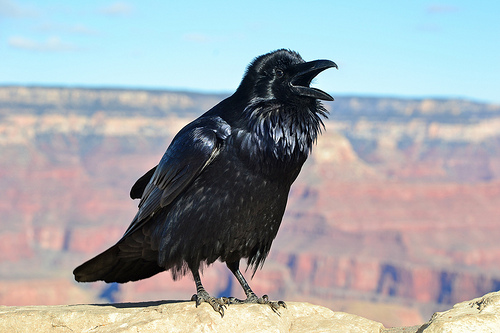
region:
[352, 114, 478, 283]
The inside of the mountain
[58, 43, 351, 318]
The bird is sitting on the mountain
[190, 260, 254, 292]
The legs on the bird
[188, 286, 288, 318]
The feet on the bird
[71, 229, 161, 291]
The tail on the bird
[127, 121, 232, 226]
The wing of the bird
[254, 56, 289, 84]
The eye of the bird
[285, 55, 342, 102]
The beak of the bird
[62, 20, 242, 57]
The sky is clear and blue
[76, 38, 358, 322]
The bird is the color black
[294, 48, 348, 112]
beak of the bird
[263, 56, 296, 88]
eye of the bird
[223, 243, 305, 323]
leg of the bird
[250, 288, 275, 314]
nail of the foot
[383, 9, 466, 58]
blue sky in the background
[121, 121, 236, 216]
black feathers on the bird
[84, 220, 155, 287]
tail feathers of the bird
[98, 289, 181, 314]
shadow on the rock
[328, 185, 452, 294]
blurry rocks in the background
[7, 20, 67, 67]
cloud in the sky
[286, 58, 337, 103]
Bird's Opened Wide Beak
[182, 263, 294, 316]
Sharp Black Bird Claws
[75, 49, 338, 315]
Black Bird Making His Calling Sound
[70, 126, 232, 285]
Silky Soft Black Wings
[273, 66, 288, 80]
Piercing All Black Eyes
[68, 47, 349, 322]
Medium Size Black Bird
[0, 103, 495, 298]
Canyons of in the distance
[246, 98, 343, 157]
Feathered out bird feathers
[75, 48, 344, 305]
Black Bird Standing Tall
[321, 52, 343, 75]
Large Pointed Tip Of Bird's Beak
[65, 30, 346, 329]
The bird's feather are shiny.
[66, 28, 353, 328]
The bird's feathers are glossy.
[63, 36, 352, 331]
The bird's feathers are black.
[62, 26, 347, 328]
The bird's beak is black.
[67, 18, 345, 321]
The bird is feathered.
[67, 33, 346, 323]
The bird's beak is open.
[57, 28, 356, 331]
The bird's talons are gripping a rock.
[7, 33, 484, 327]
The bird is alone.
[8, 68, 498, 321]
grand canyon in background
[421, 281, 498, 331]
tan rock on canyon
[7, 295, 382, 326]
tan rock on canyon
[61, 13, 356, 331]
black crow standing on rock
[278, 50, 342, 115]
crow with it's beak open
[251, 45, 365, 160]
black crow with it's beak open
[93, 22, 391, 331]
crow standing on rock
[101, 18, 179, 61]
clear blue cloudless sky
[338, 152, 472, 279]
red colored rock on canyon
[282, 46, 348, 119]
black crow's open beak